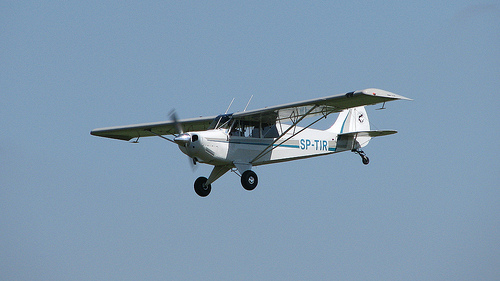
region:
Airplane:
[75, 77, 429, 194]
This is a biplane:
[78, 82, 418, 192]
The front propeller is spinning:
[147, 91, 213, 175]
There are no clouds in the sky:
[31, 25, 473, 247]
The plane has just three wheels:
[175, 156, 390, 193]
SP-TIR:
[288, 125, 344, 162]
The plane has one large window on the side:
[221, 116, 290, 141]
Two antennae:
[214, 82, 264, 116]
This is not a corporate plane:
[112, 75, 421, 187]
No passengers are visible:
[217, 103, 296, 145]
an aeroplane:
[73, 73, 467, 208]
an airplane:
[48, 63, 439, 215]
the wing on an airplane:
[72, 80, 457, 141]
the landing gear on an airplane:
[176, 149, 287, 214]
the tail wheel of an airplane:
[341, 147, 376, 170]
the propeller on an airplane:
[153, 101, 218, 192]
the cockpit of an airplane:
[208, 102, 280, 152]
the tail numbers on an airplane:
[296, 132, 336, 158]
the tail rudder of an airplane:
[331, 85, 382, 175]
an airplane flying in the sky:
[38, 58, 457, 253]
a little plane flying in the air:
[83, 86, 400, 199]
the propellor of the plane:
[151, 107, 213, 173]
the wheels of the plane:
[187, 163, 257, 196]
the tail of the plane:
[319, 91, 371, 148]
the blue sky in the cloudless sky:
[3, 3, 487, 279]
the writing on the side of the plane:
[296, 127, 331, 154]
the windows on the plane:
[218, 118, 276, 142]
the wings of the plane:
[92, 87, 402, 142]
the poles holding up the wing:
[251, 110, 329, 166]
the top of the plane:
[215, 85, 260, 125]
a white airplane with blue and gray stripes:
[86, 86, 412, 196]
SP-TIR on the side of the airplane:
[300, 138, 329, 150]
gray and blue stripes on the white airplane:
[209, 137, 299, 148]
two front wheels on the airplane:
[192, 169, 262, 197]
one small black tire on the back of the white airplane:
[360, 155, 370, 164]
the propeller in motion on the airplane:
[163, 110, 205, 170]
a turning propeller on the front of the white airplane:
[169, 109, 201, 173]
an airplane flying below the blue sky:
[12, 14, 482, 239]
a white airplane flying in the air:
[11, 12, 488, 264]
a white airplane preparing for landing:
[87, 86, 415, 196]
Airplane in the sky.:
[96, 94, 422, 169]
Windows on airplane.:
[225, 121, 282, 137]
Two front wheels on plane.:
[181, 155, 261, 197]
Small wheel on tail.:
[354, 145, 369, 164]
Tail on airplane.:
[332, 97, 378, 155]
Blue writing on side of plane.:
[299, 135, 331, 152]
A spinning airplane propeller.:
[162, 116, 201, 165]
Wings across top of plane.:
[97, 80, 392, 137]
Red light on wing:
[369, 89, 377, 98]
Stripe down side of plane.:
[212, 133, 344, 150]